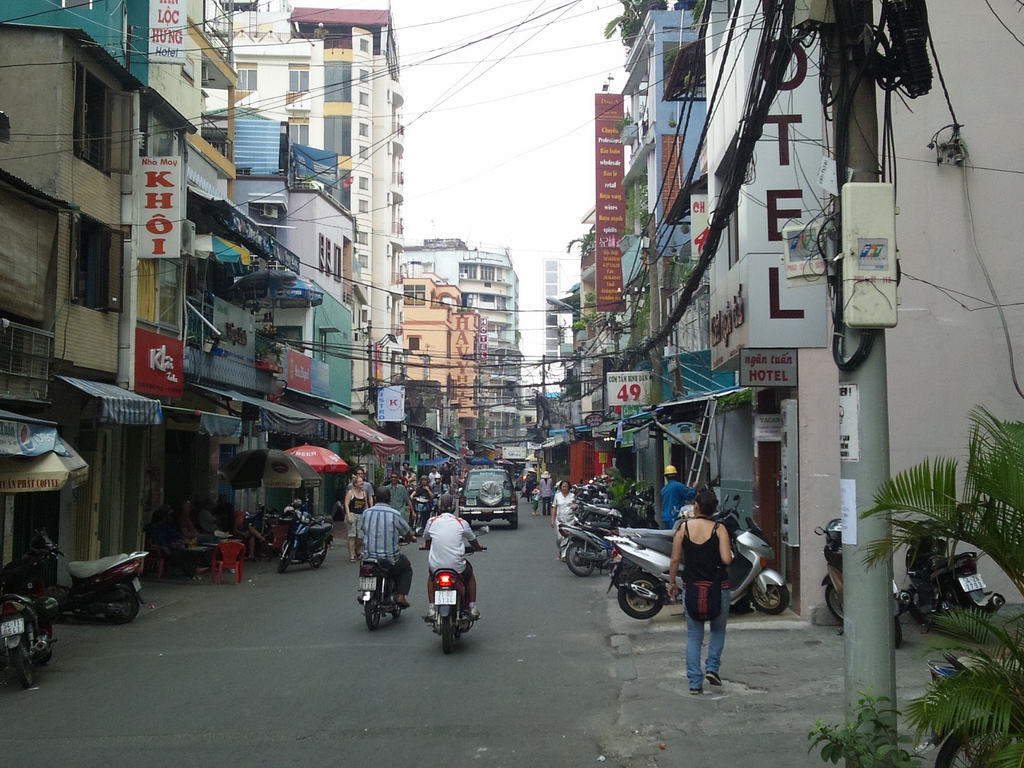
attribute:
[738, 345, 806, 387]
hotelsign — white, red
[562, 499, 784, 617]
motorcycles — parked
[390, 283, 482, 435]
building — distant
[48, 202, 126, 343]
window — glass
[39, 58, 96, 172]
window — glass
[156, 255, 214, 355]
window — glass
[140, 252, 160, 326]
window — glass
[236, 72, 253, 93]
window — glass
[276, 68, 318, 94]
window — glass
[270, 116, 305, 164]
window — glass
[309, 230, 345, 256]
window — glass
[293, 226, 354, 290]
window — glass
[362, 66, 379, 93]
window — glass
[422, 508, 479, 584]
shirt — white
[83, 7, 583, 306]
cables — black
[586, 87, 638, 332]
sign — red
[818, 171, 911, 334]
box — white